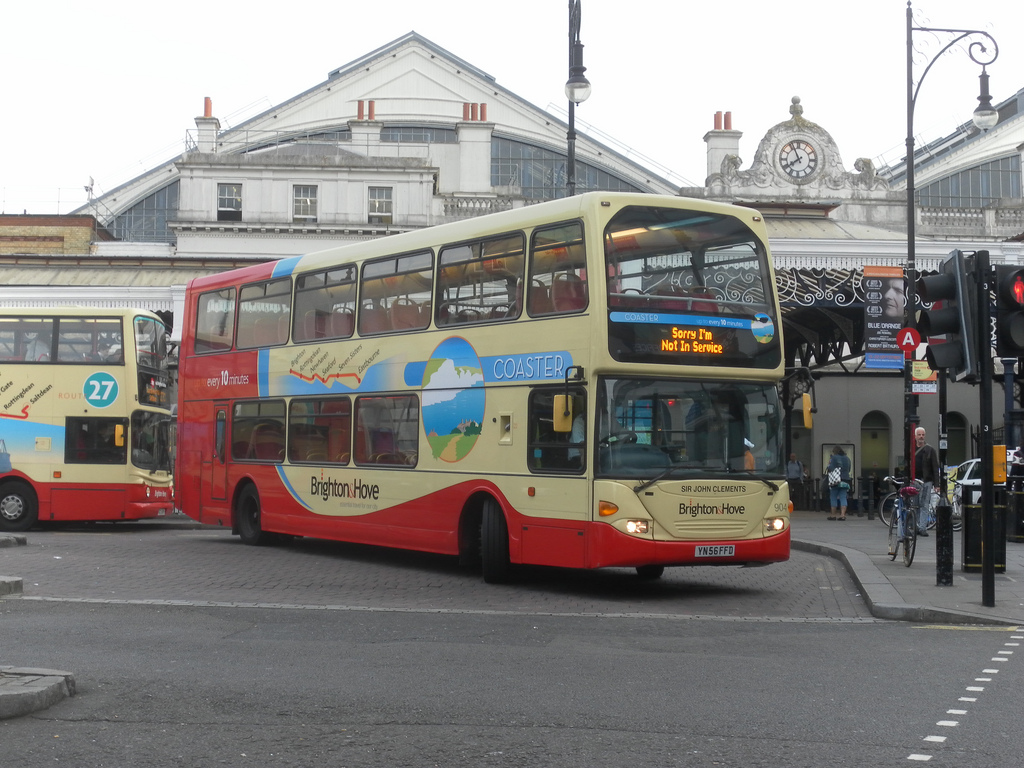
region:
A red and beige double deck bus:
[175, 186, 795, 589]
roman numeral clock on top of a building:
[769, 133, 827, 187]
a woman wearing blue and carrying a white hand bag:
[820, 440, 856, 527]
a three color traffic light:
[904, 247, 991, 390]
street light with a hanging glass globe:
[558, 0, 594, 194]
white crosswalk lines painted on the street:
[901, 627, 1019, 764]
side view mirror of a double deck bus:
[550, 364, 586, 435]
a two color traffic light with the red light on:
[989, 259, 1019, 364]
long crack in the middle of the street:
[42, 703, 875, 757]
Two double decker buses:
[0, 186, 1022, 759]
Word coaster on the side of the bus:
[487, 350, 568, 386]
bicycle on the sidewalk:
[876, 463, 927, 574]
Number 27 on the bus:
[77, 369, 122, 408]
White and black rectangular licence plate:
[689, 539, 740, 563]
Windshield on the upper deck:
[598, 198, 785, 373]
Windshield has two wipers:
[583, 362, 798, 499]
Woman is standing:
[820, 440, 858, 523]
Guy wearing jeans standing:
[892, 419, 946, 543]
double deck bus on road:
[144, 192, 803, 598]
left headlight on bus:
[757, 510, 790, 546]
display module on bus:
[621, 318, 746, 358]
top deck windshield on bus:
[612, 192, 777, 309]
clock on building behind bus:
[773, 129, 818, 187]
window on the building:
[199, 175, 253, 226]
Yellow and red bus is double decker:
[5, 298, 187, 533]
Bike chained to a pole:
[879, 470, 922, 562]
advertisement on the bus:
[408, 328, 500, 459]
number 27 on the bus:
[87, 370, 120, 403]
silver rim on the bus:
[3, 484, 27, 522]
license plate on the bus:
[692, 535, 737, 562]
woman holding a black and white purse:
[830, 464, 841, 483]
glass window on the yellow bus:
[528, 213, 593, 312]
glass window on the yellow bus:
[437, 232, 523, 327]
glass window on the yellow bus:
[361, 248, 432, 332]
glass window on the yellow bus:
[282, 264, 358, 337]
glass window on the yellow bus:
[232, 276, 296, 350]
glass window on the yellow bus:
[193, 284, 239, 355]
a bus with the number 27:
[0, 290, 184, 538]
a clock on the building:
[761, 126, 831, 206]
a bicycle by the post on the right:
[857, 464, 943, 578]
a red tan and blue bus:
[160, 165, 813, 603]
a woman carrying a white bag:
[812, 432, 863, 532]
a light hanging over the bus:
[539, 2, 610, 193]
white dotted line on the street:
[903, 617, 1021, 764]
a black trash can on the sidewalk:
[958, 474, 1016, 591]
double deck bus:
[139, 174, 813, 601]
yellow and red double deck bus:
[159, 189, 802, 613]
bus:
[88, 146, 790, 603]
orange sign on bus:
[626, 318, 735, 375]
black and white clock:
[767, 129, 831, 199]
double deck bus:
[0, 275, 177, 536]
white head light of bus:
[616, 515, 649, 545]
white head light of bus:
[749, 508, 785, 546]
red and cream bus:
[163, 184, 799, 589]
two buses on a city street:
[4, 189, 801, 583]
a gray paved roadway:
[8, 597, 1017, 766]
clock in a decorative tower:
[702, 88, 898, 207]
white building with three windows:
[172, 143, 435, 230]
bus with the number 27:
[2, 300, 171, 526]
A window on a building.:
[218, 179, 241, 217]